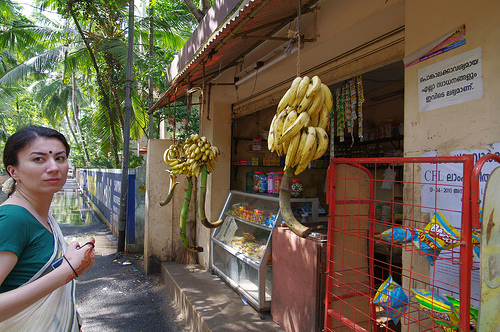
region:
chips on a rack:
[421, 213, 454, 251]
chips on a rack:
[405, 275, 456, 326]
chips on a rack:
[366, 273, 406, 316]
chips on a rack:
[362, 218, 413, 253]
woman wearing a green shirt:
[11, 105, 101, 326]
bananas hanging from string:
[281, 70, 331, 170]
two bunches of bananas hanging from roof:
[258, 2, 338, 243]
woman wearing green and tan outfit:
[0, 116, 103, 326]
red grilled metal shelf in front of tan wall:
[321, 146, 495, 326]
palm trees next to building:
[1, 0, 203, 257]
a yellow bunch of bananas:
[264, 75, 334, 172]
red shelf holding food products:
[325, 152, 481, 330]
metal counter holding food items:
[208, 187, 319, 317]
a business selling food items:
[143, 1, 495, 328]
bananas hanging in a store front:
[159, 1, 406, 181]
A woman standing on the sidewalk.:
[0, 125, 88, 330]